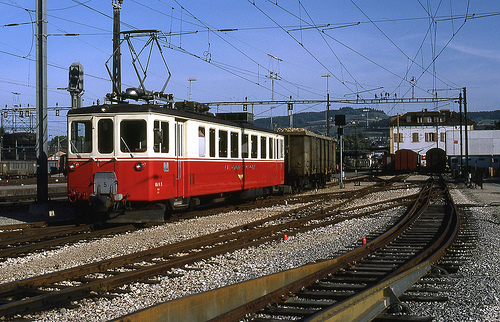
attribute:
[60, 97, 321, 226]
trolley — red bottom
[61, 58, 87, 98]
traffic lights — train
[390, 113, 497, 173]
building — white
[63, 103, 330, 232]
train — red, white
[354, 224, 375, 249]
object — orange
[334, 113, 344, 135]
sign — black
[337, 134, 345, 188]
sign post — silver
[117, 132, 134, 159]
wipers — window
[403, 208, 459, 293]
tracks — railroad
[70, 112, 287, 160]
windows — black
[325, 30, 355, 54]
power lines — electric train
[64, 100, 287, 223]
train — big, red, white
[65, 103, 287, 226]
car — train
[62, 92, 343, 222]
train — white, red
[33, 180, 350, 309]
tracks — brown, railroad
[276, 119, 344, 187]
train car — cargo carrying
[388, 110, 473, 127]
roof — brown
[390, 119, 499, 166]
house — white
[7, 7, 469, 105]
structures — metal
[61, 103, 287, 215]
engine — electric 